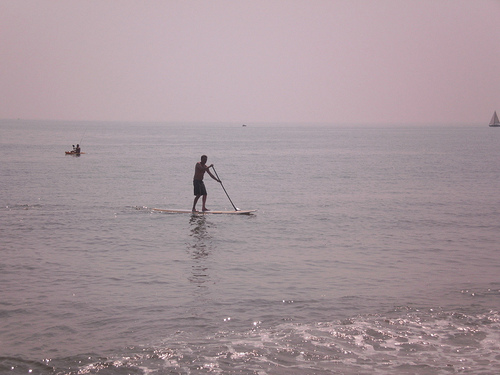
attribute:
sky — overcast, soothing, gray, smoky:
[0, 0, 499, 129]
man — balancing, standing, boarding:
[194, 155, 221, 212]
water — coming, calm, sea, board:
[1, 122, 499, 373]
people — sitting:
[65, 141, 84, 157]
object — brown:
[242, 124, 247, 129]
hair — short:
[200, 155, 206, 161]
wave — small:
[377, 303, 495, 353]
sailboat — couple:
[490, 111, 500, 128]